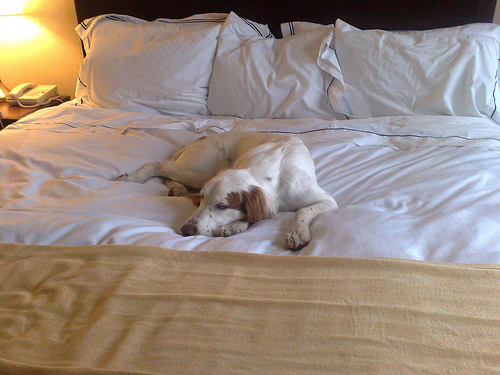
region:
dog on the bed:
[133, 111, 372, 246]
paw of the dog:
[274, 219, 328, 261]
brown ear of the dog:
[243, 194, 268, 226]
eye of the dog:
[213, 200, 229, 215]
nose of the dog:
[169, 225, 213, 237]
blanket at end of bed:
[6, 237, 468, 374]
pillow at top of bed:
[100, 9, 212, 123]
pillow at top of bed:
[218, 22, 335, 122]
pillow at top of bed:
[326, 16, 493, 119]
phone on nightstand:
[6, 78, 61, 103]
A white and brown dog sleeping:
[107, 132, 342, 253]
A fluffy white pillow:
[67, 10, 217, 120]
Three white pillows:
[71, 10, 498, 126]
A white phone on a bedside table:
[6, 76, 59, 111]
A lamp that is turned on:
[0, 11, 39, 111]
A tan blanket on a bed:
[0, 238, 498, 374]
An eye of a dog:
[212, 199, 230, 213]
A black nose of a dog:
[175, 222, 197, 239]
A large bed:
[0, 95, 498, 374]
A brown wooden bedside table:
[0, 87, 72, 132]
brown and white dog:
[126, 129, 352, 241]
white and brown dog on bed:
[6, 12, 498, 368]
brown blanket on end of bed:
[12, 233, 498, 372]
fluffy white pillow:
[72, 12, 216, 117]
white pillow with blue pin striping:
[209, 11, 345, 131]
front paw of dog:
[285, 197, 343, 261]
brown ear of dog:
[226, 185, 271, 225]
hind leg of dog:
[121, 140, 226, 187]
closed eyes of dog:
[194, 187, 230, 215]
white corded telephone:
[4, 77, 59, 109]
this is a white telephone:
[5, 82, 57, 105]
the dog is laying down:
[120, 125, 340, 245]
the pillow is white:
[80, 10, 215, 115]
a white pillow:
[330, 15, 495, 115]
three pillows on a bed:
[70, 11, 497, 112]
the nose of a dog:
[180, 220, 200, 237]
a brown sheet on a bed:
[0, 240, 495, 370]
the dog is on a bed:
[112, 126, 338, 248]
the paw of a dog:
[280, 220, 313, 253]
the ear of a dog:
[240, 181, 268, 223]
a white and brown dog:
[110, 128, 339, 251]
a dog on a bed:
[111, 129, 338, 251]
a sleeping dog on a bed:
[113, 128, 341, 250]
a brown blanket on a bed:
[0, 242, 497, 373]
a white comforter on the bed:
[0, 105, 498, 265]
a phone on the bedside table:
[6, 80, 59, 105]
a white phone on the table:
[7, 80, 59, 104]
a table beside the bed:
[0, 90, 71, 125]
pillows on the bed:
[76, 13, 498, 117]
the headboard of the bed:
[74, 0, 498, 57]